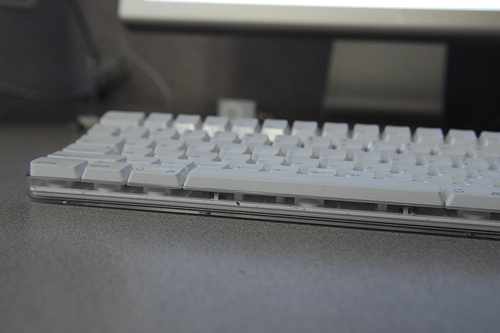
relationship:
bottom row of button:
[98, 161, 465, 198] [127, 165, 188, 190]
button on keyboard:
[122, 159, 194, 186] [55, 110, 496, 213]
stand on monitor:
[323, 39, 447, 117] [116, 2, 498, 49]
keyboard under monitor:
[26, 109, 499, 239] [116, 1, 499, 41]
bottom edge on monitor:
[116, 0, 500, 40] [116, 2, 498, 49]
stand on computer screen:
[323, 39, 447, 119] [119, 4, 499, 42]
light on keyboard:
[170, 110, 293, 141] [26, 109, 499, 239]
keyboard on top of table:
[26, 109, 499, 239] [6, 108, 498, 328]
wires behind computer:
[134, 52, 168, 92] [119, 1, 499, 72]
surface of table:
[6, 118, 495, 330] [6, 108, 498, 328]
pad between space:
[43, 181, 65, 188] [71, 176, 93, 189]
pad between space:
[97, 183, 114, 193] [121, 181, 142, 194]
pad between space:
[145, 186, 164, 197] [171, 188, 213, 201]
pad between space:
[296, 197, 318, 208] [218, 193, 234, 200]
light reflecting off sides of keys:
[172, 124, 293, 142] [30, 110, 499, 210]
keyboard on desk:
[26, 109, 499, 239] [42, 207, 443, 327]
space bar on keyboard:
[181, 164, 443, 207] [26, 109, 499, 239]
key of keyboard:
[203, 115, 226, 132] [24, 107, 499, 210]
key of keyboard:
[262, 118, 287, 136] [24, 107, 499, 210]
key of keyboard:
[324, 121, 349, 137] [24, 107, 499, 210]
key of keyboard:
[384, 125, 411, 141] [24, 107, 499, 210]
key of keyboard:
[447, 127, 477, 144] [24, 107, 499, 210]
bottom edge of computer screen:
[116, 0, 487, 40] [117, 0, 485, 40]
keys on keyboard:
[105, 108, 491, 152] [26, 92, 498, 227]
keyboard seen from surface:
[26, 109, 499, 239] [6, 118, 495, 330]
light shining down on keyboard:
[172, 124, 293, 142] [26, 92, 498, 227]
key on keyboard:
[30, 156, 88, 178] [26, 109, 499, 239]